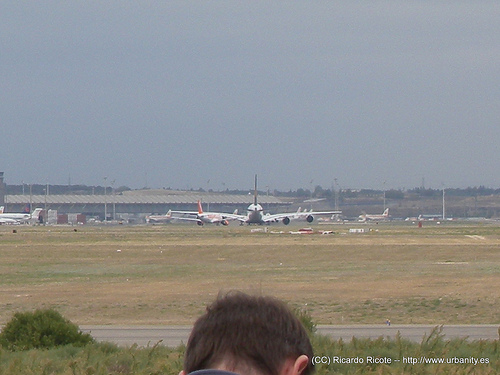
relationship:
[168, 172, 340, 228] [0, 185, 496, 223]
plane in airport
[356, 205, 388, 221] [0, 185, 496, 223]
plane in airport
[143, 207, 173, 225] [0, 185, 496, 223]
plane in airport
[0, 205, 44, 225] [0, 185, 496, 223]
plane in airport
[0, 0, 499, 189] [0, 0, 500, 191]
clouds in blue sky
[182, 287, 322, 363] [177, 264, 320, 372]
hair on head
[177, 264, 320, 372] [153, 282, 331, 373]
head of man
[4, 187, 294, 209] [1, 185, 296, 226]
roof on building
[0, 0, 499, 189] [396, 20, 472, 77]
clouds in blue sky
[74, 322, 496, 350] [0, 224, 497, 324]
road near field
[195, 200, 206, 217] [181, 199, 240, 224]
tail on plane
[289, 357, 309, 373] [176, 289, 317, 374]
ear of man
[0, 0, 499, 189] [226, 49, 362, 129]
clouds in sky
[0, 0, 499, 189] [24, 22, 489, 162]
clouds in sky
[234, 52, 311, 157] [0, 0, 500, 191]
clouds in blue sky